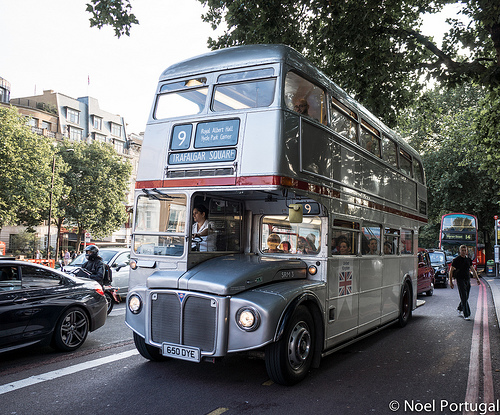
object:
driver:
[192, 205, 217, 252]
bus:
[123, 43, 429, 387]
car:
[0, 260, 107, 360]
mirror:
[285, 188, 303, 223]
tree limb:
[199, 0, 498, 85]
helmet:
[83, 245, 99, 261]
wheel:
[185, 234, 203, 242]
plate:
[162, 342, 201, 363]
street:
[408, 330, 468, 395]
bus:
[439, 213, 495, 272]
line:
[0, 347, 141, 396]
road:
[0, 262, 500, 415]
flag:
[338, 270, 354, 296]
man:
[449, 244, 481, 320]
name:
[388, 399, 500, 415]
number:
[178, 131, 186, 146]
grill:
[151, 293, 216, 352]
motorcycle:
[58, 260, 122, 315]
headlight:
[234, 305, 261, 332]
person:
[75, 245, 105, 287]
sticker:
[337, 256, 354, 320]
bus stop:
[476, 248, 485, 265]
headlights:
[127, 293, 143, 314]